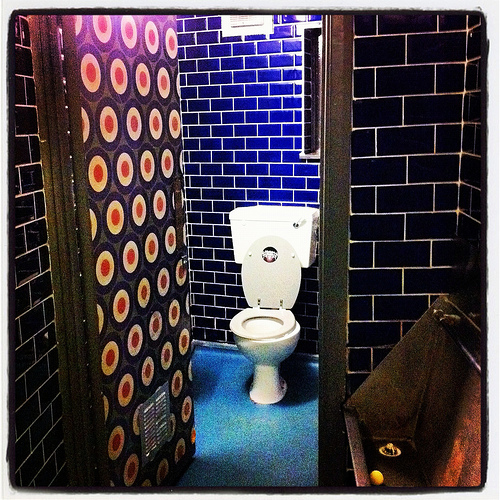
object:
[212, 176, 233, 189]
tile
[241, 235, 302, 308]
lid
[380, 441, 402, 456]
drain system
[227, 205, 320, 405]
toilet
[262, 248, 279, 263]
sticker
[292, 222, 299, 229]
flusher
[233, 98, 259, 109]
tile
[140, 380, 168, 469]
vent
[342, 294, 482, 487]
metal tub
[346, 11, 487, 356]
wall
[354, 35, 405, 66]
tiles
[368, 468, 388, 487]
ball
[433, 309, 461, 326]
faucet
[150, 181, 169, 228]
circle design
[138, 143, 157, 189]
circle design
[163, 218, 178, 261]
circle design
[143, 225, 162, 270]
circle design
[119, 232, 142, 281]
circle design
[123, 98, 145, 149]
circle design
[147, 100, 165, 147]
circle design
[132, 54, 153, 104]
circle design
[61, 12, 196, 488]
door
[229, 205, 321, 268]
tank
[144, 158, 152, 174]
bullseye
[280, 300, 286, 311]
hinges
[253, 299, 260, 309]
hinges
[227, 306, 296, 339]
toilet seat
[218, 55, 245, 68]
brick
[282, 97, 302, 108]
brick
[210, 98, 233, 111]
brick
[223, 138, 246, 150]
brick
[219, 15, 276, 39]
white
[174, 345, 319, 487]
floor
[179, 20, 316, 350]
wall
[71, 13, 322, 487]
bathroom